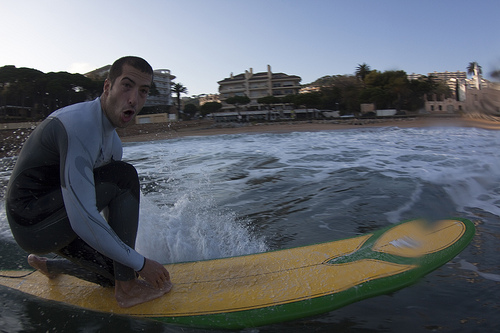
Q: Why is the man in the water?
A: To surf.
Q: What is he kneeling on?
A: Surfboard.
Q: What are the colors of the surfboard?
A: Yellow and green.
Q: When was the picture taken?
A: Evening.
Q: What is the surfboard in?
A: Water.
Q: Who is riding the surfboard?
A: A man.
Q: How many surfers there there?
A: One.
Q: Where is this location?
A: Beach.